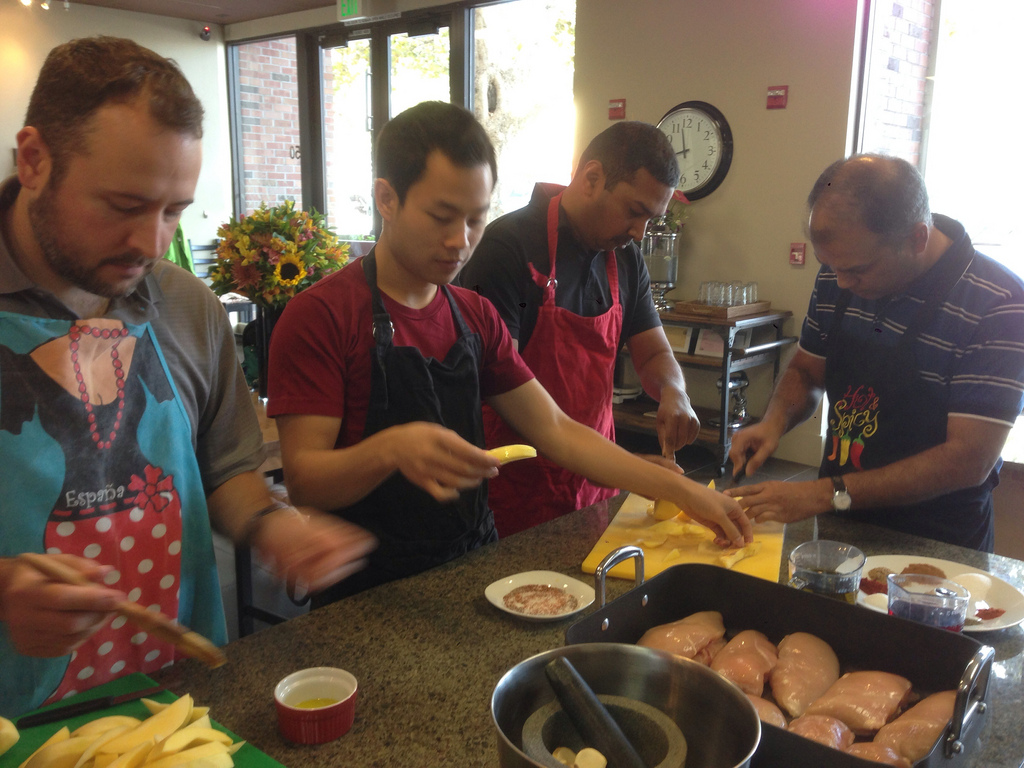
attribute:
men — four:
[29, 17, 993, 638]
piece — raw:
[711, 620, 776, 705]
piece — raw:
[767, 631, 845, 725]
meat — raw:
[802, 648, 921, 741]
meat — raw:
[858, 689, 962, 763]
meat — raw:
[709, 622, 779, 703]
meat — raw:
[855, 723, 933, 763]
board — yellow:
[572, 477, 795, 588]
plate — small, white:
[471, 555, 605, 622]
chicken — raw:
[631, 589, 966, 764]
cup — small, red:
[259, 652, 374, 748]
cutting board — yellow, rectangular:
[579, 481, 798, 592]